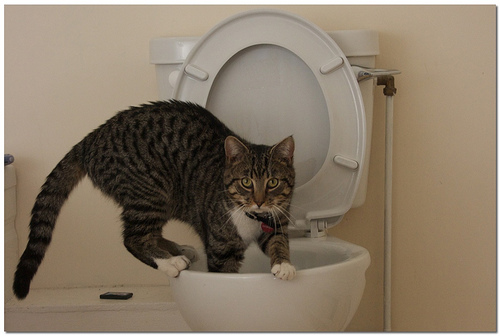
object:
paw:
[272, 270, 296, 281]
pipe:
[382, 95, 394, 334]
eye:
[241, 178, 253, 189]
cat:
[10, 98, 307, 302]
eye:
[267, 179, 278, 188]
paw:
[163, 256, 192, 277]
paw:
[181, 247, 200, 263]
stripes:
[122, 130, 197, 175]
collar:
[245, 211, 282, 229]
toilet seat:
[170, 9, 369, 231]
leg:
[267, 224, 290, 264]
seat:
[169, 10, 372, 231]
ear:
[224, 135, 250, 158]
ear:
[271, 135, 295, 164]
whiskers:
[214, 199, 301, 242]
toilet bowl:
[169, 236, 370, 333]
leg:
[207, 244, 245, 272]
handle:
[351, 65, 401, 82]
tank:
[203, 43, 330, 190]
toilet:
[163, 10, 371, 334]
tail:
[11, 145, 85, 301]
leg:
[124, 207, 174, 271]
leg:
[151, 217, 182, 258]